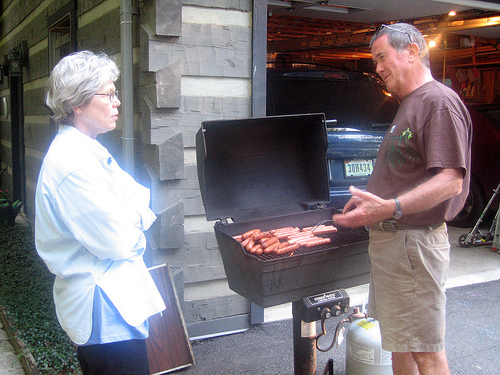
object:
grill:
[249, 226, 358, 259]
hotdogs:
[264, 240, 282, 253]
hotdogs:
[262, 237, 279, 247]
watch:
[393, 197, 404, 220]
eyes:
[104, 89, 117, 104]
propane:
[343, 314, 392, 375]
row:
[269, 186, 305, 279]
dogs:
[275, 244, 299, 256]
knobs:
[300, 288, 357, 322]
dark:
[413, 144, 469, 170]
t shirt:
[360, 82, 472, 233]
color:
[404, 178, 455, 208]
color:
[385, 271, 448, 332]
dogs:
[306, 238, 332, 249]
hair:
[38, 50, 114, 121]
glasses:
[89, 88, 119, 103]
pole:
[287, 305, 334, 375]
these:
[256, 247, 263, 254]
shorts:
[369, 228, 450, 349]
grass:
[14, 329, 50, 375]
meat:
[258, 213, 336, 239]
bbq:
[233, 255, 333, 326]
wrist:
[387, 197, 408, 223]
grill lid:
[193, 110, 333, 225]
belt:
[366, 219, 444, 231]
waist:
[363, 211, 453, 233]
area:
[1, 220, 63, 371]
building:
[1, 0, 491, 338]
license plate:
[344, 157, 374, 177]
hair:
[365, 21, 432, 70]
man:
[328, 21, 474, 375]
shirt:
[32, 121, 166, 346]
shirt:
[364, 76, 475, 227]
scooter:
[455, 180, 484, 225]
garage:
[239, 2, 484, 317]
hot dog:
[301, 237, 324, 247]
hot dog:
[265, 242, 281, 253]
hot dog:
[250, 229, 274, 241]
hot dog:
[238, 227, 260, 239]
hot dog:
[312, 226, 338, 234]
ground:
[2, 221, 484, 371]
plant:
[2, 222, 47, 338]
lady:
[32, 47, 167, 375]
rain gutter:
[117, 0, 138, 180]